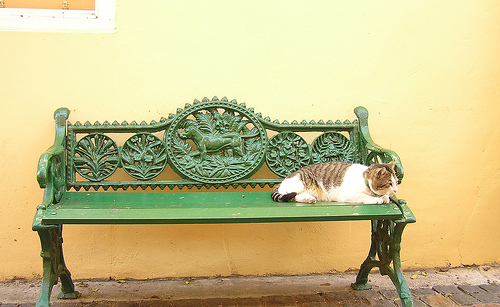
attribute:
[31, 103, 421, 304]
bench — metal, green, one, old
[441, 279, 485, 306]
brick — one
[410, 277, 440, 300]
brick — one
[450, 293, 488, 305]
brick — one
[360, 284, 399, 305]
brick — one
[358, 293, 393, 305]
brick — one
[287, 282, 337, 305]
brick — one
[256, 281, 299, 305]
brick — one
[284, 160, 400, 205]
cat — one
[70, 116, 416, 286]
bench — green